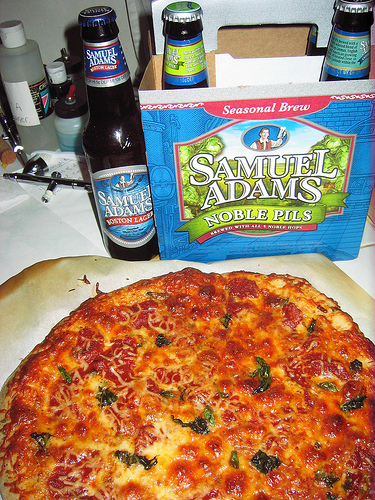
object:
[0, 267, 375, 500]
pizza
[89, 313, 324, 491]
surface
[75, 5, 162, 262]
bottle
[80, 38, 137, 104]
neck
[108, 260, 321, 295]
edge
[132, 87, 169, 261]
edge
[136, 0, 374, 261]
box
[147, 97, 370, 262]
surface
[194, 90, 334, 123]
red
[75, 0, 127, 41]
top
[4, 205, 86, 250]
desktop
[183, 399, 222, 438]
basil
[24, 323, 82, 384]
crust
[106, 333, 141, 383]
lines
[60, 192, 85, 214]
paper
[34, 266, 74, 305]
board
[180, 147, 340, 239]
words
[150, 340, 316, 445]
cheese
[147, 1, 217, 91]
beer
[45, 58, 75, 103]
bottle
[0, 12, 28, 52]
cap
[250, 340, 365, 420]
vegetables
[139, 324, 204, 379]
tomatoes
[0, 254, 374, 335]
parchment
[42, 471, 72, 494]
pepper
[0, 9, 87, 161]
supplies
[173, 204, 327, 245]
ribbon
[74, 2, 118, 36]
caps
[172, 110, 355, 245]
picture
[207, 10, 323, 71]
handle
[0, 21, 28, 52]
lid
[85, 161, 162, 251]
sticker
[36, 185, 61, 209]
tape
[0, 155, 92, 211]
metal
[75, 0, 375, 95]
three